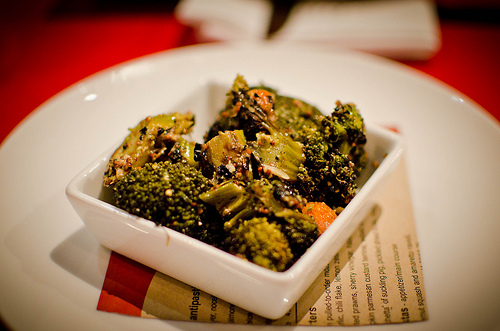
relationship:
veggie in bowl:
[101, 72, 378, 270] [57, 71, 412, 324]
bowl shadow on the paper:
[52, 204, 388, 327] [90, 113, 429, 324]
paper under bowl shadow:
[90, 113, 429, 324] [52, 204, 388, 327]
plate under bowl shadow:
[0, 45, 485, 328] [52, 204, 388, 327]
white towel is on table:
[144, 4, 458, 74] [16, 9, 485, 328]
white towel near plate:
[144, 4, 458, 74] [0, 45, 485, 328]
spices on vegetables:
[114, 155, 150, 175] [128, 87, 333, 246]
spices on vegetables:
[230, 151, 260, 176] [128, 87, 333, 246]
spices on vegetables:
[227, 77, 297, 118] [128, 87, 333, 246]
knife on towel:
[262, 0, 299, 41] [172, 1, 438, 61]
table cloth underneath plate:
[43, 24, 108, 48] [37, 81, 476, 328]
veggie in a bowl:
[101, 72, 378, 270] [57, 71, 412, 324]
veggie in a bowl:
[101, 72, 378, 270] [51, 38, 427, 322]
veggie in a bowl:
[219, 72, 292, 137] [374, 125, 426, 185]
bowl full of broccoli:
[57, 71, 412, 324] [113, 158, 213, 231]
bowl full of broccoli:
[57, 71, 412, 324] [212, 216, 295, 271]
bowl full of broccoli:
[57, 71, 412, 324] [301, 127, 359, 204]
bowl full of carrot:
[57, 71, 412, 324] [300, 197, 337, 234]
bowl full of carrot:
[57, 71, 412, 324] [224, 86, 276, 116]